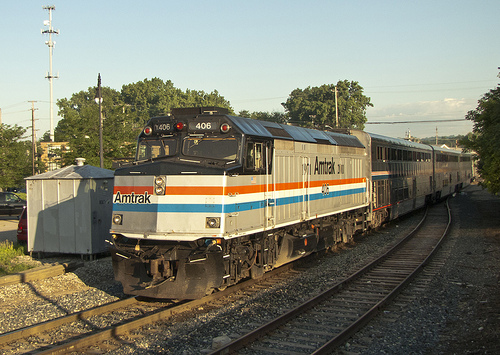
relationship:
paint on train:
[231, 131, 279, 184] [78, 73, 485, 305]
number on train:
[195, 121, 212, 130] [108, 99, 493, 304]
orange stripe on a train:
[112, 185, 224, 195] [108, 99, 493, 304]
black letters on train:
[116, 190, 152, 207] [108, 99, 493, 304]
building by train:
[22, 157, 115, 261] [108, 99, 493, 304]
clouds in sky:
[426, 100, 465, 112] [3, 0, 498, 78]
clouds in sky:
[369, 100, 417, 120] [3, 0, 498, 78]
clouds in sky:
[290, 42, 348, 62] [3, 0, 498, 78]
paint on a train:
[184, 186, 230, 196] [108, 99, 493, 304]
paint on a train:
[195, 193, 218, 205] [108, 99, 493, 304]